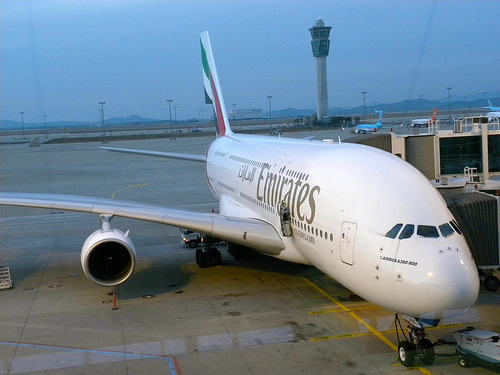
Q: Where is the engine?
A: On the wing.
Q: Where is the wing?
A: On the jet.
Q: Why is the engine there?
A: To fly the plane.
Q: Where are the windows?
A: On the plane.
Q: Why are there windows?
A: To see out of the plane.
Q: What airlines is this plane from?
A: Emirates.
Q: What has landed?
A: A plane.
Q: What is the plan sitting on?
A: The concrete.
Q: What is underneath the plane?
A: The wheels.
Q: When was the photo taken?
A: Daytime.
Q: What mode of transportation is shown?
A: Plane.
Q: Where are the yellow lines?
A: Pavement.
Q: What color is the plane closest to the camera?
A: White.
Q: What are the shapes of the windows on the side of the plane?
A: Oval.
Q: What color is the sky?
A: Blue.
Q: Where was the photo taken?
A: At an airport.